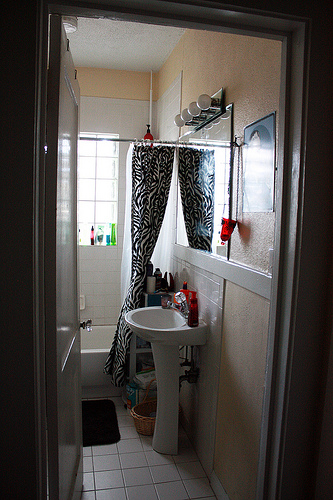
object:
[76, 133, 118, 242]
window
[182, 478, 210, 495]
white tile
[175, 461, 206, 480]
white tile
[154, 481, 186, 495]
white tile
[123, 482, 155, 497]
white tile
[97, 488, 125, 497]
white tile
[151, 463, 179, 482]
white tile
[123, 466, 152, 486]
white tile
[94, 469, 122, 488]
white tile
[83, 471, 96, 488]
white tile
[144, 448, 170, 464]
white tile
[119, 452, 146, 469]
white tile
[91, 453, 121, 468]
white tile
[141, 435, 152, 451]
white tile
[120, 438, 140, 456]
white tile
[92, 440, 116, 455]
white tile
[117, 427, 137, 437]
white tile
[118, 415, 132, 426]
white tile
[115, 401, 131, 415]
white tile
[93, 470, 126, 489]
tile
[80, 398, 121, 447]
rug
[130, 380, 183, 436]
basket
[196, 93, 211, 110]
globes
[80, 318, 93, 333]
door knob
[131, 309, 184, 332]
sink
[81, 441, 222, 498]
floor